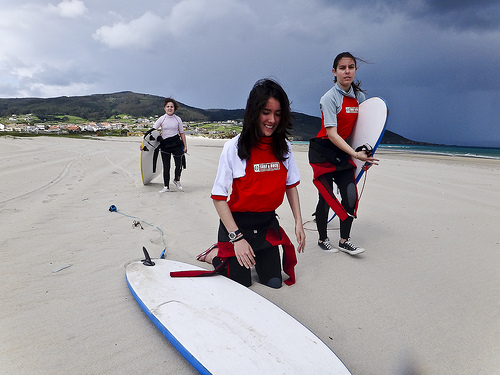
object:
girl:
[196, 76, 305, 289]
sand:
[3, 131, 499, 374]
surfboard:
[125, 258, 354, 374]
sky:
[1, 1, 499, 147]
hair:
[236, 77, 294, 162]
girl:
[307, 49, 380, 256]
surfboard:
[327, 96, 390, 221]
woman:
[153, 98, 188, 193]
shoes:
[340, 240, 365, 256]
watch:
[226, 229, 245, 240]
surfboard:
[140, 128, 160, 186]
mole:
[263, 134, 269, 136]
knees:
[260, 275, 284, 289]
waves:
[379, 144, 410, 148]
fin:
[140, 245, 155, 266]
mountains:
[0, 91, 409, 143]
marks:
[0, 157, 72, 202]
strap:
[169, 269, 226, 277]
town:
[0, 109, 291, 139]